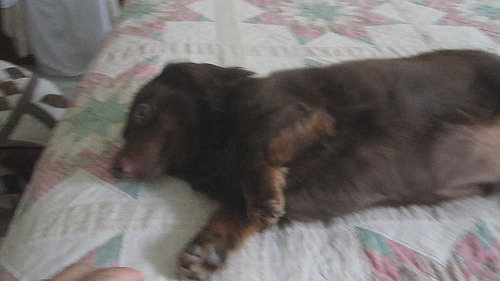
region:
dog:
[119, 42, 498, 227]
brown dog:
[94, 52, 480, 208]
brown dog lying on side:
[98, 57, 486, 210]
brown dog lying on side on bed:
[95, 48, 444, 239]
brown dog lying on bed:
[101, 40, 475, 240]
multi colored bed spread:
[133, 7, 472, 44]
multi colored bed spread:
[291, 232, 475, 273]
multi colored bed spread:
[76, 117, 115, 269]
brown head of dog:
[110, 58, 235, 195]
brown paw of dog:
[174, 234, 229, 276]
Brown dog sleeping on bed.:
[105, 45, 499, 279]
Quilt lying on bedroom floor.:
[0, 53, 74, 240]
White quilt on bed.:
[0, 0, 498, 279]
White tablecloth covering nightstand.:
[0, 0, 125, 79]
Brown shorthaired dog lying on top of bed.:
[107, 45, 498, 279]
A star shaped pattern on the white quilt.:
[241, 0, 399, 50]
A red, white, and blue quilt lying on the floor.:
[0, 55, 73, 244]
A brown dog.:
[105, 45, 498, 278]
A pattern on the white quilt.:
[97, 0, 215, 47]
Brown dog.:
[107, 43, 499, 279]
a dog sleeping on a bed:
[93, 13, 499, 278]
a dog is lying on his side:
[88, 32, 497, 279]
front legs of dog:
[168, 116, 313, 278]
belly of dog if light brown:
[348, 107, 499, 222]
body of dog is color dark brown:
[155, 35, 495, 117]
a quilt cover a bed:
[5, 0, 495, 280]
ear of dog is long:
[151, 40, 262, 100]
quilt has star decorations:
[235, 1, 405, 56]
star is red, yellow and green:
[241, 0, 413, 55]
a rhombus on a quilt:
[1, 162, 145, 279]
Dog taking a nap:
[98, 42, 443, 279]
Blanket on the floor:
[0, 54, 72, 159]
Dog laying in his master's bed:
[91, 41, 457, 279]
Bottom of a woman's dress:
[0, 0, 147, 80]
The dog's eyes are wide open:
[105, 87, 173, 136]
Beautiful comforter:
[237, 1, 417, 51]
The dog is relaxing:
[101, 40, 459, 280]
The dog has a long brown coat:
[98, 40, 492, 257]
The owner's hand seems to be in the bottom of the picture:
[38, 246, 155, 279]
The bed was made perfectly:
[46, 25, 372, 279]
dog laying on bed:
[108, 47, 495, 279]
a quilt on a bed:
[9, 1, 496, 279]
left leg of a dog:
[237, 100, 333, 235]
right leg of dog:
[175, 198, 260, 278]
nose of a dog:
[101, 154, 132, 186]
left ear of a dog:
[164, 58, 255, 117]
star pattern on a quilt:
[245, 1, 406, 54]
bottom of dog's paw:
[176, 239, 218, 279]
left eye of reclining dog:
[127, 92, 158, 129]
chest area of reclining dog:
[278, 127, 382, 241]